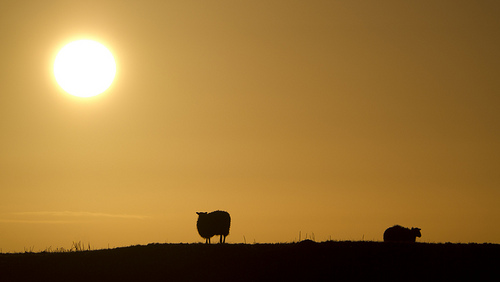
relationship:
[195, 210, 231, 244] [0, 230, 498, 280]
sheep are standing in grass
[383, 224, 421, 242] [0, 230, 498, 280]
sheep are standing in grass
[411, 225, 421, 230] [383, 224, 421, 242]
ears for sheep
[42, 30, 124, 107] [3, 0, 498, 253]
sun in sky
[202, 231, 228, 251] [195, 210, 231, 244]
legs on sheep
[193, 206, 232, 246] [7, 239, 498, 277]
sheep on hill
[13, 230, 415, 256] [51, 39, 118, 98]
grass blades against sun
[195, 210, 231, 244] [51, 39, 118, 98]
sheep during sun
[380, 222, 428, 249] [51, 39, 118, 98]
sheep resting during sun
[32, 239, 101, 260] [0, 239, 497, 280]
grass on ground